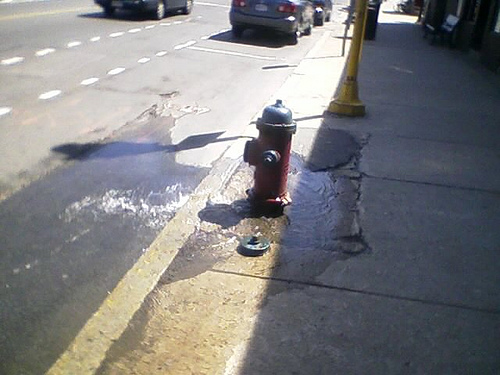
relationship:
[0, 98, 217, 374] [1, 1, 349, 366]
water on road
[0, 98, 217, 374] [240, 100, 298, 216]
water from fire hydrant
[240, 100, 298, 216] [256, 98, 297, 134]
fire hydrant has top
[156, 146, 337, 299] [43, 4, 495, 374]
water on sidewalk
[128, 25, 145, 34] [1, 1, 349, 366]
line on road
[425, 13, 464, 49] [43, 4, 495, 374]
bench on sidewalk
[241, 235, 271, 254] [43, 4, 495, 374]
cap on ground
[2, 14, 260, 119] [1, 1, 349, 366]
line in street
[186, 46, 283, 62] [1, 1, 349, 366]
line in street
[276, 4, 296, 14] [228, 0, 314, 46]
light on car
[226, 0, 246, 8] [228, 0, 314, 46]
light on car